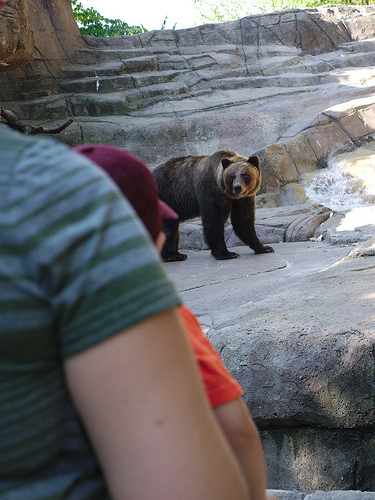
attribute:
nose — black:
[230, 173, 254, 192]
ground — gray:
[157, 240, 373, 390]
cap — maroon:
[75, 144, 184, 230]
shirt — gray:
[4, 123, 184, 498]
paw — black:
[253, 243, 274, 254]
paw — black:
[212, 251, 239, 259]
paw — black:
[161, 253, 188, 260]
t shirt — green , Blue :
[0, 120, 189, 495]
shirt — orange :
[180, 302, 245, 408]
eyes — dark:
[220, 169, 259, 184]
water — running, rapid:
[298, 167, 372, 209]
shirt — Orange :
[174, 299, 242, 406]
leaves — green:
[301, 0, 374, 11]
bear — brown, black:
[147, 147, 276, 263]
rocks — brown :
[48, 11, 301, 144]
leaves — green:
[96, 13, 122, 27]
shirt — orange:
[67, 144, 266, 498]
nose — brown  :
[232, 184, 242, 193]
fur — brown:
[171, 160, 212, 203]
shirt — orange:
[161, 277, 253, 414]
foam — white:
[305, 159, 363, 213]